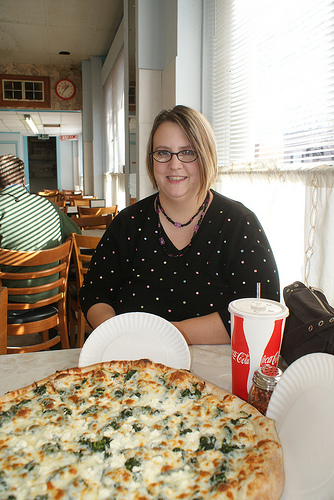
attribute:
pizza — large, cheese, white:
[0, 356, 286, 498]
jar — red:
[246, 365, 282, 417]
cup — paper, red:
[228, 298, 290, 402]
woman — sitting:
[76, 105, 284, 344]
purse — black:
[275, 277, 333, 369]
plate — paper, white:
[78, 309, 194, 371]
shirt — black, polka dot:
[76, 188, 283, 337]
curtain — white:
[208, 166, 333, 301]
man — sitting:
[0, 153, 88, 321]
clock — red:
[52, 75, 77, 102]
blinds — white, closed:
[202, 1, 333, 167]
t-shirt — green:
[0, 180, 83, 317]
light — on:
[24, 116, 42, 139]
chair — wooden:
[0, 233, 75, 357]